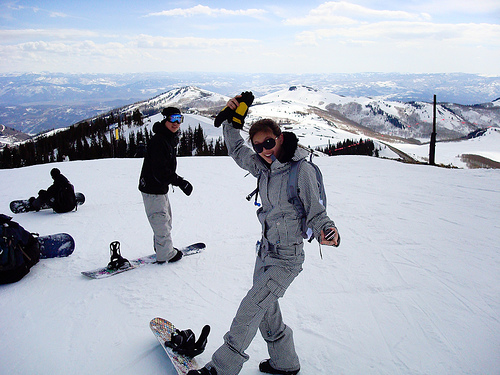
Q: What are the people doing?
A: Snowboarding.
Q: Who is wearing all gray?
A: The woman.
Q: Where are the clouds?
A: In the sky.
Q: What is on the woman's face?
A: Ski goggles.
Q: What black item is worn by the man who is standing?
A: A jacket.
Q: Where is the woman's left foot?
A: On a snowboard.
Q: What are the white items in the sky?
A: Clouds.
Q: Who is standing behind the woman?
A: A man.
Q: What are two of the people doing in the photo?
A: Standing.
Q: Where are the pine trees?
A: On the mountain.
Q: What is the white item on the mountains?
A: Snow.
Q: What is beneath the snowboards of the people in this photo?
A: Snow.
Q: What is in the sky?
A: Clouds.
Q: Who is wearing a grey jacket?
A: The woman.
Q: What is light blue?
A: Sky.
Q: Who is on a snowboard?
A: The man.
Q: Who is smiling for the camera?
A: The person in grey.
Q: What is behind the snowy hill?
A: Mountains.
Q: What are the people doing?
A: Standing on the snow.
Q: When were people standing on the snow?
A: Daytime.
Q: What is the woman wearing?
A: A suit.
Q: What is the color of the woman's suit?
A: Gray.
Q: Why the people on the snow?
A: To snowboard.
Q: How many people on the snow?
A: Three.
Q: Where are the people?
A: On the snow.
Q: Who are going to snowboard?
A: The people.